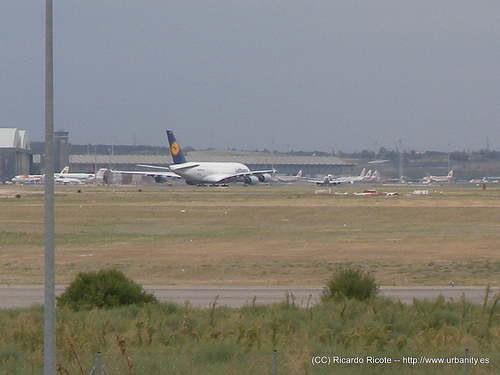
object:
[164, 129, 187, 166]
tail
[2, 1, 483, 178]
distance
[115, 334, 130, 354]
weed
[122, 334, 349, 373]
weed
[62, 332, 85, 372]
weed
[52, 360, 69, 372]
weed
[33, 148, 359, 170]
airport terminal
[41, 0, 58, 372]
lamp post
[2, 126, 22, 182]
airplane hangar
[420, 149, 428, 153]
house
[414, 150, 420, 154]
house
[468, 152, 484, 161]
house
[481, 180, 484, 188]
fire hydrant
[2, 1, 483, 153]
sky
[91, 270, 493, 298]
runway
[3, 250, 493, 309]
long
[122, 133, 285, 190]
airplane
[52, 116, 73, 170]
large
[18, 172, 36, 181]
window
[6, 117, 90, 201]
portion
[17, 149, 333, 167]
roof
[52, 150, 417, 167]
building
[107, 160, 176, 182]
white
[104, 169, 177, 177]
wing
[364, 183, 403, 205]
large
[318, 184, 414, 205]
red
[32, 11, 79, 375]
pole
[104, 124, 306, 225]
plane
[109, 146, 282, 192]
white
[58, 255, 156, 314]
bush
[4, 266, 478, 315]
road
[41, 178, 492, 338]
airport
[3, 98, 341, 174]
hangar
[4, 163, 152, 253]
smaller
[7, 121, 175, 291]
planes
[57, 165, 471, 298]
passenger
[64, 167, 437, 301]
area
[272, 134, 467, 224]
airplanes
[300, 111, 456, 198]
flight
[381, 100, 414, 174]
tower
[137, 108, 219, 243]
navy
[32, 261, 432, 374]
strip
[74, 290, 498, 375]
bushes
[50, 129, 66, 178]
control tower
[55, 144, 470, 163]
tree line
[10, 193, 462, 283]
field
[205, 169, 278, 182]
wing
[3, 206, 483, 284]
airport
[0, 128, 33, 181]
hangers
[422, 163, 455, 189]
airplane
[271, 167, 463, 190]
planes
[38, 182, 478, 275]
field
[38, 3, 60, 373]
light pole